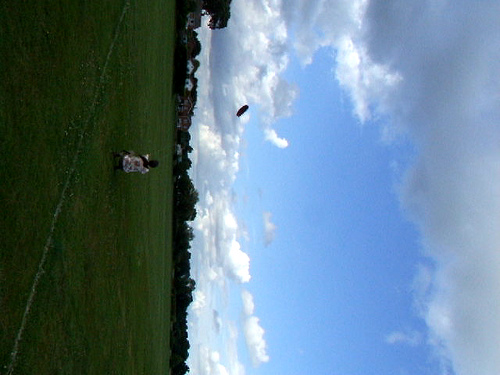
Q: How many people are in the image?
A: 1.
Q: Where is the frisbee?
A: In the air.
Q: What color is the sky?
A: Blue.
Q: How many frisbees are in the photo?
A: 1.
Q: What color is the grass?
A: Green.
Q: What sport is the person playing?
A: Frisbee.